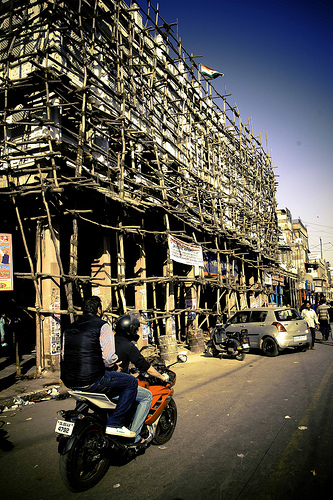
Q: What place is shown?
A: It is a street.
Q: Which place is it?
A: It is a street.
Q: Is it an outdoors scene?
A: Yes, it is outdoors.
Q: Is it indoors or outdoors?
A: It is outdoors.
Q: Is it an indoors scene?
A: No, it is outdoors.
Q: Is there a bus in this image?
A: No, there are no buses.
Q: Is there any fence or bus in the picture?
A: No, there are no buses or fences.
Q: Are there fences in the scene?
A: No, there are no fences.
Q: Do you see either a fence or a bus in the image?
A: No, there are no fences or buses.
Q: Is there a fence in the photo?
A: No, there are no fences.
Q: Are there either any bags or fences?
A: No, there are no fences or bags.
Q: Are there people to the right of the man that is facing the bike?
A: Yes, there is a person to the right of the man.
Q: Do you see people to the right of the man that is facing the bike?
A: Yes, there is a person to the right of the man.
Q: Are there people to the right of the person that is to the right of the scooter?
A: Yes, there is a person to the right of the man.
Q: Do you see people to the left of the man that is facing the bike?
A: No, the person is to the right of the man.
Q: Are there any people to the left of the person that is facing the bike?
A: No, the person is to the right of the man.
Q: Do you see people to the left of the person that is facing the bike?
A: No, the person is to the right of the man.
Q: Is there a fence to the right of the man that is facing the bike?
A: No, there is a person to the right of the man.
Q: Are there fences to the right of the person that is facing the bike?
A: No, there is a person to the right of the man.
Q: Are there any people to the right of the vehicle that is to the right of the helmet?
A: Yes, there is a person to the right of the SUV.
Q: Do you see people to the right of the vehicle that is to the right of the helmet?
A: Yes, there is a person to the right of the SUV.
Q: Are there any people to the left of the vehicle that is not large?
A: No, the person is to the right of the SUV.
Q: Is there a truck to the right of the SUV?
A: No, there is a person to the right of the SUV.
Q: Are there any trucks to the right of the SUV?
A: No, there is a person to the right of the SUV.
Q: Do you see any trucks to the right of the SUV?
A: No, there is a person to the right of the SUV.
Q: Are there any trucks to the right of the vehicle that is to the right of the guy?
A: No, there is a person to the right of the SUV.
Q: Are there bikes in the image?
A: Yes, there is a bike.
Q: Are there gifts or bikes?
A: Yes, there is a bike.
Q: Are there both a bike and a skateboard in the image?
A: No, there is a bike but no skateboards.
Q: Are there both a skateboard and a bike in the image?
A: No, there is a bike but no skateboards.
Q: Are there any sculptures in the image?
A: No, there are no sculptures.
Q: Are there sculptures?
A: No, there are no sculptures.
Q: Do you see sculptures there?
A: No, there are no sculptures.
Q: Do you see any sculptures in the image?
A: No, there are no sculptures.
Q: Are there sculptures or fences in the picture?
A: No, there are no sculptures or fences.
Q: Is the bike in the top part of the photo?
A: No, the bike is in the bottom of the image.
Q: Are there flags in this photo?
A: Yes, there is a flag.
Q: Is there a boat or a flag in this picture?
A: Yes, there is a flag.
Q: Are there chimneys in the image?
A: No, there are no chimneys.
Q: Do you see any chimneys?
A: No, there are no chimneys.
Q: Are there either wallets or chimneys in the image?
A: No, there are no chimneys or wallets.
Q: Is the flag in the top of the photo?
A: Yes, the flag is in the top of the image.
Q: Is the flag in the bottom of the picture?
A: No, the flag is in the top of the image.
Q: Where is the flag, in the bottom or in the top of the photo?
A: The flag is in the top of the image.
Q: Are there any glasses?
A: No, there are no glasses.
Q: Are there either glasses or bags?
A: No, there are no glasses or bags.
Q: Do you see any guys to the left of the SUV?
A: Yes, there is a guy to the left of the SUV.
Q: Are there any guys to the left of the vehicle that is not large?
A: Yes, there is a guy to the left of the SUV.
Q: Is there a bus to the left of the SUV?
A: No, there is a guy to the left of the SUV.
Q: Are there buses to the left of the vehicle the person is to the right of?
A: No, there is a guy to the left of the SUV.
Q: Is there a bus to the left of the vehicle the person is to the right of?
A: No, there is a guy to the left of the SUV.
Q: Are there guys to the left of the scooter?
A: Yes, there is a guy to the left of the scooter.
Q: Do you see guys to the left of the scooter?
A: Yes, there is a guy to the left of the scooter.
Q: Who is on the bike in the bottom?
A: The guy is on the bike.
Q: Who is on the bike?
A: The guy is on the bike.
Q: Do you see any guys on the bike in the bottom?
A: Yes, there is a guy on the bike.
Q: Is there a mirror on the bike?
A: No, there is a guy on the bike.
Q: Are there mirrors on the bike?
A: No, there is a guy on the bike.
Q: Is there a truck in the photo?
A: No, there are no trucks.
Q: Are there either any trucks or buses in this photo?
A: No, there are no trucks or buses.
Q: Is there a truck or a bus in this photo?
A: No, there are no trucks or buses.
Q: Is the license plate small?
A: Yes, the license plate is small.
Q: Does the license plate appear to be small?
A: Yes, the license plate is small.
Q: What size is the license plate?
A: The license plate is small.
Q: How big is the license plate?
A: The license plate is small.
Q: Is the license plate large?
A: No, the license plate is small.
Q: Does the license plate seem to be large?
A: No, the license plate is small.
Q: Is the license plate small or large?
A: The license plate is small.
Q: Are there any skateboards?
A: No, there are no skateboards.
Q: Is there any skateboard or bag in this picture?
A: No, there are no skateboards or bags.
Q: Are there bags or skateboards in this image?
A: No, there are no skateboards or bags.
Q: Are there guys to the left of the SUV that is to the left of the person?
A: Yes, there is a guy to the left of the SUV.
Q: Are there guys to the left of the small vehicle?
A: Yes, there is a guy to the left of the SUV.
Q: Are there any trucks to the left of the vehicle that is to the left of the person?
A: No, there is a guy to the left of the SUV.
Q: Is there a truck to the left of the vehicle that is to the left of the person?
A: No, there is a guy to the left of the SUV.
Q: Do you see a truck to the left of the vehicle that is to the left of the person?
A: No, there is a guy to the left of the SUV.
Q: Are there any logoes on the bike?
A: No, there is a guy on the bike.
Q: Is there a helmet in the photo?
A: Yes, there is a helmet.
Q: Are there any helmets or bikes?
A: Yes, there is a helmet.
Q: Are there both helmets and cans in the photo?
A: No, there is a helmet but no cans.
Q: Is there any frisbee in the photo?
A: No, there are no frisbees.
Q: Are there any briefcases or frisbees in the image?
A: No, there are no frisbees or briefcases.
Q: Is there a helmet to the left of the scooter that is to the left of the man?
A: Yes, there is a helmet to the left of the scooter.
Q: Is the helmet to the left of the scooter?
A: Yes, the helmet is to the left of the scooter.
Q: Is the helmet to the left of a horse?
A: No, the helmet is to the left of the scooter.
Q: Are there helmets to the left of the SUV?
A: Yes, there is a helmet to the left of the SUV.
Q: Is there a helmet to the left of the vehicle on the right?
A: Yes, there is a helmet to the left of the SUV.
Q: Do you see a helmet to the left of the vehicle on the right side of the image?
A: Yes, there is a helmet to the left of the SUV.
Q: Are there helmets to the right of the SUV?
A: No, the helmet is to the left of the SUV.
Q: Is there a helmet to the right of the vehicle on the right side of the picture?
A: No, the helmet is to the left of the SUV.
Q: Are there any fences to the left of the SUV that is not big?
A: No, there is a helmet to the left of the SUV.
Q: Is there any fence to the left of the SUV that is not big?
A: No, there is a helmet to the left of the SUV.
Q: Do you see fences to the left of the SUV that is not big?
A: No, there is a helmet to the left of the SUV.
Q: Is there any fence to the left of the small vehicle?
A: No, there is a helmet to the left of the SUV.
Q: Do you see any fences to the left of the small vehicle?
A: No, there is a helmet to the left of the SUV.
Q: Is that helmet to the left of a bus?
A: No, the helmet is to the left of the SUV.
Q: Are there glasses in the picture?
A: No, there are no glasses.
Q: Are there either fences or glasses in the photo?
A: No, there are no fences or glasses.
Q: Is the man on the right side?
A: Yes, the man is on the right of the image.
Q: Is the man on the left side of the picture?
A: No, the man is on the right of the image.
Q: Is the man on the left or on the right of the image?
A: The man is on the right of the image.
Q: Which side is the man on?
A: The man is on the right of the image.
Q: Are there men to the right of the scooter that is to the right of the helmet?
A: Yes, there is a man to the right of the scooter.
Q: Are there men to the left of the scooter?
A: No, the man is to the right of the scooter.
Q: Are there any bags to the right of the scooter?
A: No, there is a man to the right of the scooter.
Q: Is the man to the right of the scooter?
A: Yes, the man is to the right of the scooter.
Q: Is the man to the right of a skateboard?
A: No, the man is to the right of the scooter.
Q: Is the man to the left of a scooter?
A: No, the man is to the right of a scooter.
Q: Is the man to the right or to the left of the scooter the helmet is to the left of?
A: The man is to the right of the scooter.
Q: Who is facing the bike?
A: The man is facing the bike.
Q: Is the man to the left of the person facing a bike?
A: Yes, the man is facing a bike.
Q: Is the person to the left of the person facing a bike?
A: Yes, the man is facing a bike.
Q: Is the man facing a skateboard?
A: No, the man is facing a bike.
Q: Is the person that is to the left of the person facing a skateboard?
A: No, the man is facing a bike.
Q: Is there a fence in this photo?
A: No, there are no fences.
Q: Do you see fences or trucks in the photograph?
A: No, there are no fences or trucks.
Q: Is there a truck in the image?
A: No, there are no trucks.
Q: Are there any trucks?
A: No, there are no trucks.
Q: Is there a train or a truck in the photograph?
A: No, there are no trucks or trains.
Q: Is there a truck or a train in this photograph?
A: No, there are no trucks or trains.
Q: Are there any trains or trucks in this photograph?
A: No, there are no trucks or trains.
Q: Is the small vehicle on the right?
A: Yes, the SUV is on the right of the image.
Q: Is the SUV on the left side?
A: No, the SUV is on the right of the image.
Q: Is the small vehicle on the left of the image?
A: No, the SUV is on the right of the image.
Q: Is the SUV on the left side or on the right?
A: The SUV is on the right of the image.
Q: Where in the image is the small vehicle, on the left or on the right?
A: The SUV is on the right of the image.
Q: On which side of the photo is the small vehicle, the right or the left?
A: The SUV is on the right of the image.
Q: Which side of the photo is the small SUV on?
A: The SUV is on the right of the image.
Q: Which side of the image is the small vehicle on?
A: The SUV is on the right of the image.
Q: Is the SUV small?
A: Yes, the SUV is small.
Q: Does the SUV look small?
A: Yes, the SUV is small.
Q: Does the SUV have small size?
A: Yes, the SUV is small.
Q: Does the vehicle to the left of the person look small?
A: Yes, the SUV is small.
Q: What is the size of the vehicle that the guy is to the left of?
A: The SUV is small.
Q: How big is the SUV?
A: The SUV is small.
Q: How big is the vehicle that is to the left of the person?
A: The SUV is small.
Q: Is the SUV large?
A: No, the SUV is small.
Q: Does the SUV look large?
A: No, the SUV is small.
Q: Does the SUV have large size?
A: No, the SUV is small.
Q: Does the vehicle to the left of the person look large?
A: No, the SUV is small.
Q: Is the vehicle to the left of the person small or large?
A: The SUV is small.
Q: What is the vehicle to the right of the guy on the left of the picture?
A: The vehicle is a SUV.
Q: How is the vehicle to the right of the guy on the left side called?
A: The vehicle is a SUV.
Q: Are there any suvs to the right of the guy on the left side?
A: Yes, there is a SUV to the right of the guy.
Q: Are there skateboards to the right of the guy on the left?
A: No, there is a SUV to the right of the guy.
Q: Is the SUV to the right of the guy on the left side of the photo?
A: Yes, the SUV is to the right of the guy.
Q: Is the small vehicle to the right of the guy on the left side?
A: Yes, the SUV is to the right of the guy.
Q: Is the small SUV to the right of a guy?
A: Yes, the SUV is to the right of a guy.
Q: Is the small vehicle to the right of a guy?
A: Yes, the SUV is to the right of a guy.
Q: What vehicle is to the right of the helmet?
A: The vehicle is a SUV.